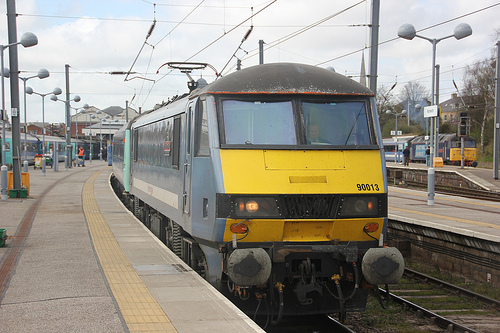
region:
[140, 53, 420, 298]
Blue and yellow train on train track.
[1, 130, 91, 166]
Blue side of train.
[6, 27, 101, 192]
Lamp posts lining the walkway of train station.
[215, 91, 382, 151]
Front windows on black and yellow train.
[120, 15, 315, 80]
Electrical cables attached to top of train.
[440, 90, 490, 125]
Red brick building next to train tracks.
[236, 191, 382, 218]
Headlights in front of train.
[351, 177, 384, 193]
Train's number written in black.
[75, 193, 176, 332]
Yellow inlaid brick on walkway.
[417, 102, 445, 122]
White sign on lamppost.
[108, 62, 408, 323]
train is yellow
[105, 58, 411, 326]
train on tracks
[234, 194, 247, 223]
orange light on train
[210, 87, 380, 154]
window on train is square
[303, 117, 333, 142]
conductor driving the train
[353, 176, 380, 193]
black number on train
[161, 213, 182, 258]
wheel on train is black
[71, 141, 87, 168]
man in orange working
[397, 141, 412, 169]
man waiting for train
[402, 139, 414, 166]
man wearing black sweater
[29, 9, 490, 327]
a trains pulls into a station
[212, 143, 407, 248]
yellow paint on a train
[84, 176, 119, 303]
yellow bricks along a platform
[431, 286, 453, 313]
grass growing on train tracks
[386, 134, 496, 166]
two people waiting on another train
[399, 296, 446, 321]
metal rails of a train track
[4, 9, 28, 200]
a metal pole supported by a green base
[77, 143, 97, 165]
a man in an orange jacket waits on the train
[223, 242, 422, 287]
round metal front brakes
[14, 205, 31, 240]
red brick lines the platform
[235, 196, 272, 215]
The working headlight on the front of the train.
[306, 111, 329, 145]
The conductor sitting in the front of the train.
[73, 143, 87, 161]
The person wearing an orange vest.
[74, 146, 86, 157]
The black sweater the person in the orange vest has on.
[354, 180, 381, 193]
The numbers on the front of the train.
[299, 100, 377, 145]
The right window on the front of the train.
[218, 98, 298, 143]
The left window on the front of the train.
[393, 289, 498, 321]
The railroad tracks to the right of the train.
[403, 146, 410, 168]
The person standing on the platform to the right of the main pictured train.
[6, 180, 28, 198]
The green bin against the pole where a yellow square box is placed on the platform to the left.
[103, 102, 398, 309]
the train is on the track.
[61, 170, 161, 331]
The line in the middle of the sidewalk is yellow.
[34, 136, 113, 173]
People are standing around waiting for the train.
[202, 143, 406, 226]
The train is yellow in the front.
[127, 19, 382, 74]
A lot of wires above the train.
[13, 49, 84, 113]
A lot of street lights on the sidewalk.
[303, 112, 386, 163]
A driver sits in the train.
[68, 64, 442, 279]
A train is parked at a train station.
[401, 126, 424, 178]
a person is standing on the other side of the track.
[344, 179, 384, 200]
Black numbers are written on the train.